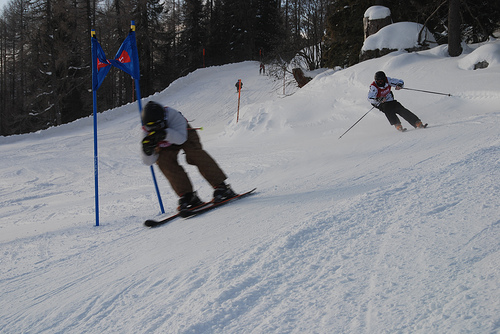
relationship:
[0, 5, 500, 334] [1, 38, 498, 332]
rough snow on hill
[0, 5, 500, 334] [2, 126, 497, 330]
rough snow on hill side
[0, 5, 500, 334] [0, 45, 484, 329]
rough snow on hill side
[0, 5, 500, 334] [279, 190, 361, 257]
rough snow on hill side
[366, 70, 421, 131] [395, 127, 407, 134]
person on ski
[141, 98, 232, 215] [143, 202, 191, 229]
person on ski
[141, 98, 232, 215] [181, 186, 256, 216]
person on ski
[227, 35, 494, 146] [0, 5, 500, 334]
hill of rough snow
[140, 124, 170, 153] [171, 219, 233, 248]
snow gear to protect against snow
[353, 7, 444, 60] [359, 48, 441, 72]
depth of snow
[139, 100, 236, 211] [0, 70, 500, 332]
person on slope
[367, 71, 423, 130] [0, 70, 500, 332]
person on slope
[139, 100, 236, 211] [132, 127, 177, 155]
person leaning into hands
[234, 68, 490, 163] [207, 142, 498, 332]
smooth snow next to rough snow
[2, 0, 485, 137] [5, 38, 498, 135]
trees at top of slopes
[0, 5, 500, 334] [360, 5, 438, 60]
rough snow over building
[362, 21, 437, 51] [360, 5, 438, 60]
snow over building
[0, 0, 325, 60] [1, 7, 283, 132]
sky through branches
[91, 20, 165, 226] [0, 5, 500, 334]
flag sticking out from rough snow